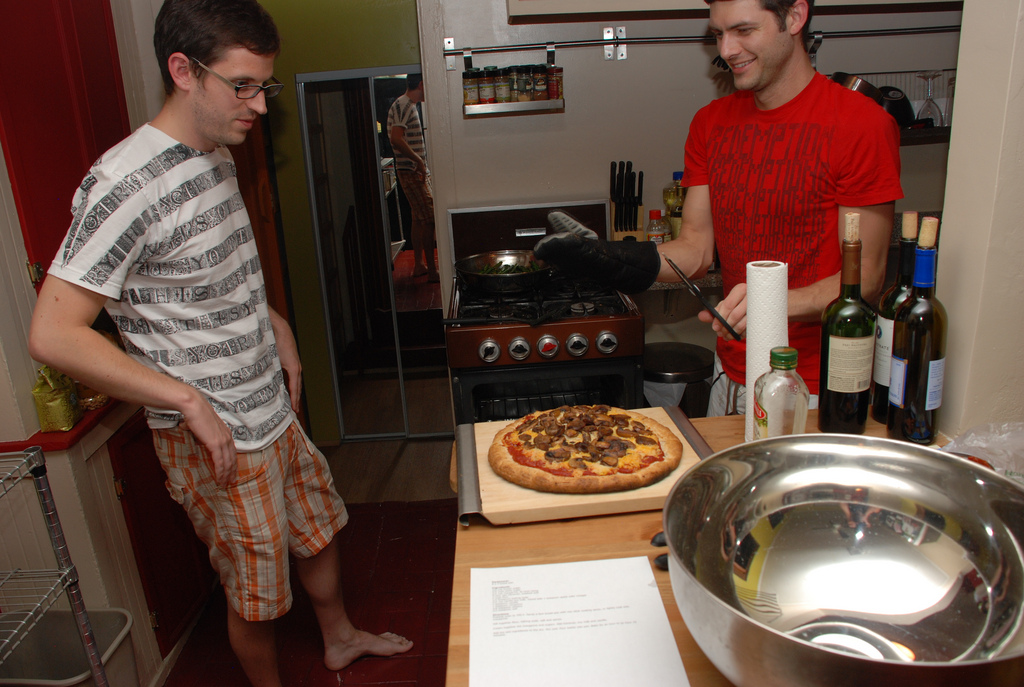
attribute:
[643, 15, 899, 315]
man — cooking, young, standing, white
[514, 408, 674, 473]
pizza — done, yellow, large, cooked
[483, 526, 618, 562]
table — brown, close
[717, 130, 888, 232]
shirt — red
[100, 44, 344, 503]
guy — close, white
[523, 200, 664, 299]
mitt — black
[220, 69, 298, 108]
glasses — black